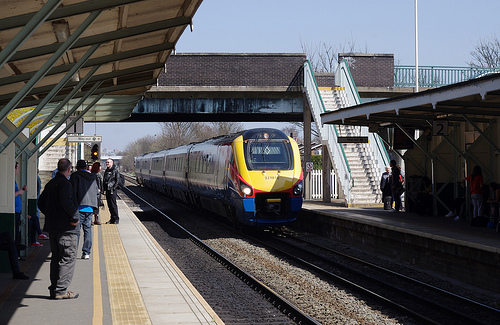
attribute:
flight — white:
[307, 62, 396, 206]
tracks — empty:
[133, 190, 299, 318]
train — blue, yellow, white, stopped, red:
[128, 123, 321, 223]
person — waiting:
[36, 153, 89, 307]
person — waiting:
[72, 158, 97, 260]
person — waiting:
[99, 152, 122, 230]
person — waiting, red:
[462, 164, 488, 227]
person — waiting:
[385, 160, 409, 209]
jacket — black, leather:
[103, 166, 123, 194]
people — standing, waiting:
[5, 139, 127, 305]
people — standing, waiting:
[371, 149, 496, 230]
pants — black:
[101, 184, 122, 226]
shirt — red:
[461, 170, 488, 197]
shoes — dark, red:
[470, 212, 486, 227]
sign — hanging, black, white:
[333, 130, 385, 150]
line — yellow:
[86, 195, 146, 324]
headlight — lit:
[239, 181, 256, 198]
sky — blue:
[190, 1, 496, 70]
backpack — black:
[113, 169, 125, 190]